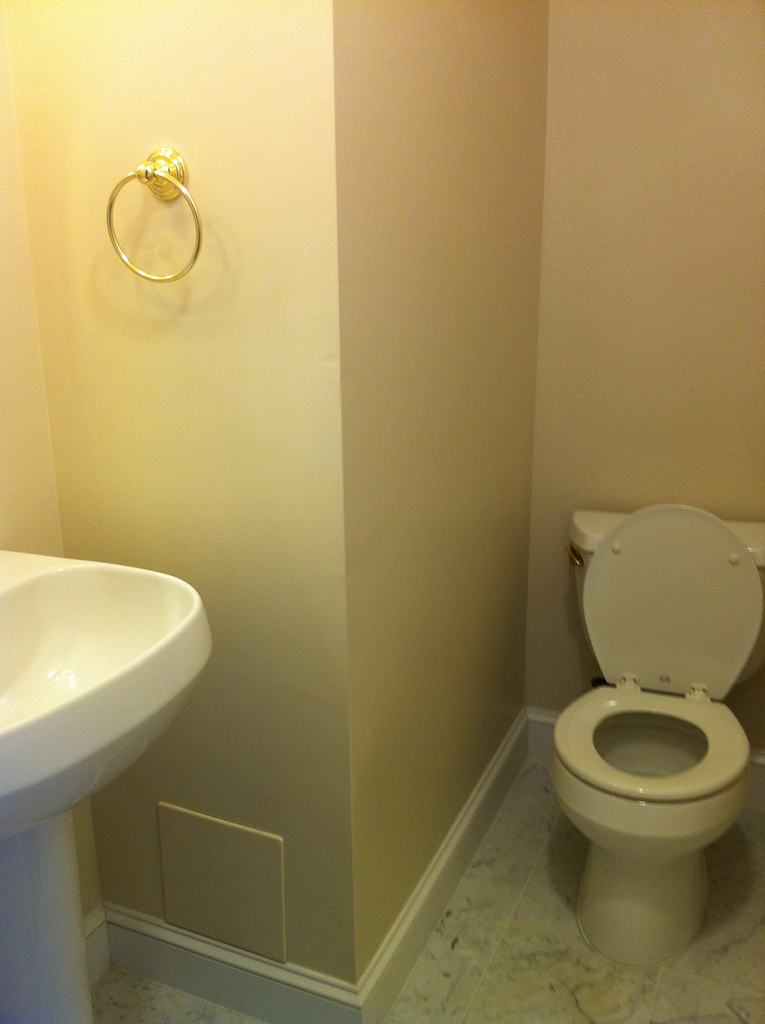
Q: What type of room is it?
A: It is a bathroom.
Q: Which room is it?
A: It is a bathroom.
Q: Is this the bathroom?
A: Yes, it is the bathroom.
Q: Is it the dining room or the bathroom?
A: It is the bathroom.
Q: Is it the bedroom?
A: No, it is the bathroom.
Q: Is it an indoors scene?
A: Yes, it is indoors.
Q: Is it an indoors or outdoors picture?
A: It is indoors.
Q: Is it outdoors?
A: No, it is indoors.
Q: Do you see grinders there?
A: No, there are no grinders.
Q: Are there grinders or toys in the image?
A: No, there are no grinders or toys.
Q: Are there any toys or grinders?
A: No, there are no grinders or toys.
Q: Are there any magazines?
A: No, there are no magazines.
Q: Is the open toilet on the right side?
A: Yes, the toilet is on the right of the image.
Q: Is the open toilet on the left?
A: No, the toilet is on the right of the image.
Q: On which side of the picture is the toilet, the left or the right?
A: The toilet is on the right of the image.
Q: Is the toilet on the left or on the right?
A: The toilet is on the right of the image.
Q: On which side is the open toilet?
A: The toilet is on the right of the image.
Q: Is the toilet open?
A: Yes, the toilet is open.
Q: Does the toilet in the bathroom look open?
A: Yes, the toilet is open.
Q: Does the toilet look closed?
A: No, the toilet is open.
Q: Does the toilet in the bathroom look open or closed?
A: The toilet is open.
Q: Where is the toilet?
A: The toilet is in the bathroom.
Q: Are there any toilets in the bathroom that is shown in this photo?
A: Yes, there is a toilet in the bathroom.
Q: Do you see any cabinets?
A: No, there are no cabinets.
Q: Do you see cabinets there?
A: No, there are no cabinets.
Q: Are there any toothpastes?
A: No, there are no toothpastes.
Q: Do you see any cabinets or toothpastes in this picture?
A: No, there are no toothpastes or cabinets.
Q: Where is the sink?
A: The sink is in the bathroom.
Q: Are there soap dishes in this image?
A: No, there are no soap dishes.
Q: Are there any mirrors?
A: No, there are no mirrors.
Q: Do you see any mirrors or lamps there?
A: No, there are no mirrors or lamps.